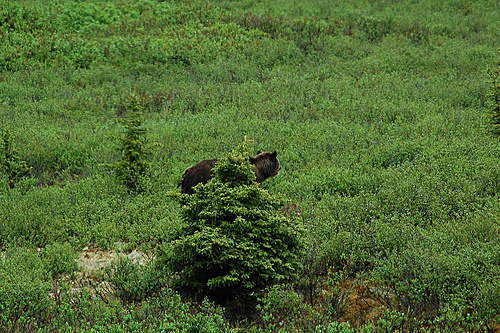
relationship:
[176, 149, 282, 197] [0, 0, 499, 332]
bear in plants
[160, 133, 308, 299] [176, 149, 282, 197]
tree in front of bear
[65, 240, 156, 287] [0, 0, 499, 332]
dirt in plants